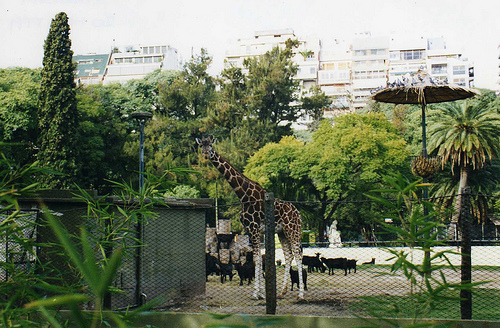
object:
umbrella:
[371, 67, 476, 106]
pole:
[417, 102, 429, 269]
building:
[67, 35, 498, 127]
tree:
[288, 114, 409, 236]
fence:
[0, 194, 499, 326]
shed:
[3, 189, 213, 306]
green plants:
[0, 181, 173, 328]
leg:
[290, 235, 305, 301]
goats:
[206, 250, 256, 286]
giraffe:
[193, 135, 307, 302]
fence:
[25, 199, 499, 321]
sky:
[0, 0, 494, 93]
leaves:
[33, 11, 88, 190]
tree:
[27, 12, 81, 202]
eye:
[199, 145, 203, 148]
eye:
[209, 144, 213, 147]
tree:
[405, 90, 499, 320]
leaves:
[363, 172, 490, 316]